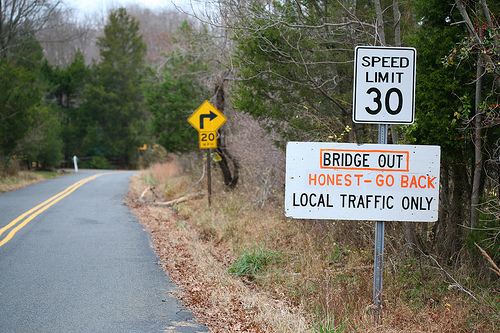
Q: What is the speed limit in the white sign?
A: 30.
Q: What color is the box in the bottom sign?
A: Orange.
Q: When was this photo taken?
A: Daytime.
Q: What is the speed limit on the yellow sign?
A: 20.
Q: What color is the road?
A: Grey.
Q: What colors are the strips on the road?
A: Yellow.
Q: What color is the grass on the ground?
A: Brown.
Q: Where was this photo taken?
A: In the road outside.